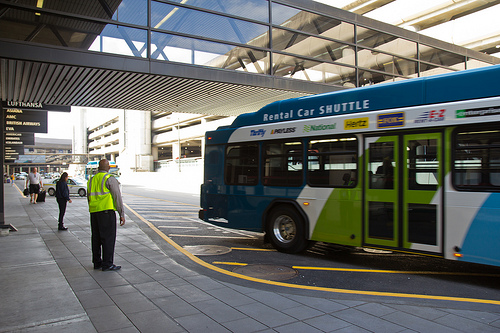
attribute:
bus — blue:
[172, 63, 497, 268]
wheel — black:
[263, 197, 311, 254]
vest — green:
[82, 171, 122, 216]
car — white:
[39, 175, 92, 196]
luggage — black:
[22, 187, 48, 203]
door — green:
[366, 134, 444, 252]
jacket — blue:
[55, 181, 73, 203]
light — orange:
[301, 198, 312, 210]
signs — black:
[0, 99, 51, 163]